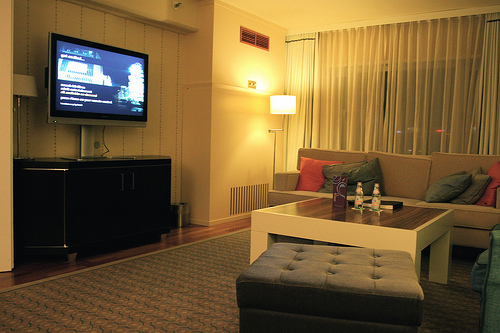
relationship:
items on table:
[353, 199, 403, 211] [250, 197, 455, 284]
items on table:
[370, 182, 384, 217] [250, 197, 455, 284]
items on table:
[353, 182, 365, 212] [250, 197, 455, 284]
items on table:
[330, 177, 347, 210] [250, 197, 455, 284]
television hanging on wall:
[41, 27, 161, 144] [151, 0, 493, 197]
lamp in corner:
[269, 89, 296, 114] [258, 23, 304, 190]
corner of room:
[258, 23, 304, 190] [1, 1, 496, 331]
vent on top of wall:
[239, 27, 271, 49] [1, 0, 287, 270]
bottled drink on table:
[348, 177, 365, 212] [355, 210, 408, 240]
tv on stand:
[45, 30, 173, 156] [65, 127, 117, 159]